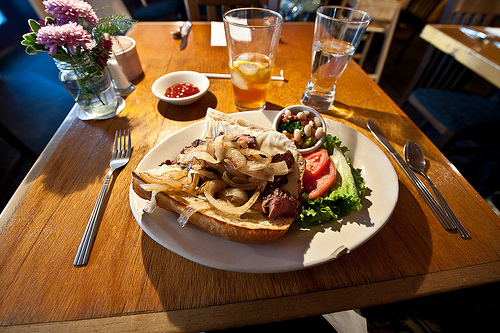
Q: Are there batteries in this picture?
A: No, there are no batteries.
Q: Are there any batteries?
A: No, there are no batteries.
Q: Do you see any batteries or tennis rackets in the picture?
A: No, there are no batteries or tennis rackets.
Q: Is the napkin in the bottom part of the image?
A: No, the napkin is in the top of the image.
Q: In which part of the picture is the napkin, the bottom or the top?
A: The napkin is in the top of the image.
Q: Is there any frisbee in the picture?
A: No, there are no frisbees.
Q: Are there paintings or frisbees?
A: No, there are no frisbees or paintings.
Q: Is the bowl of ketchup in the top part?
A: Yes, the bowl is in the top of the image.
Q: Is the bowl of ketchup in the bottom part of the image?
A: No, the bowl is in the top of the image.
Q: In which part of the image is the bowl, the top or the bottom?
A: The bowl is in the top of the image.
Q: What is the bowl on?
A: The bowl is on the table.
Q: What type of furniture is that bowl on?
A: The bowl is on the table.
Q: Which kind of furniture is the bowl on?
A: The bowl is on the table.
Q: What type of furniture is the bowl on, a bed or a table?
A: The bowl is on a table.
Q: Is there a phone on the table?
A: No, there is a bowl on the table.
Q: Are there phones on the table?
A: No, there is a bowl on the table.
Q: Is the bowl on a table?
A: Yes, the bowl is on a table.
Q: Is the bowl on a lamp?
A: No, the bowl is on a table.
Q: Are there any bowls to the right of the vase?
A: Yes, there is a bowl to the right of the vase.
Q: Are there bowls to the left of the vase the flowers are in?
A: No, the bowl is to the right of the vase.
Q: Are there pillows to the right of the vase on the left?
A: No, there is a bowl to the right of the vase.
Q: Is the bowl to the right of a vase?
A: Yes, the bowl is to the right of a vase.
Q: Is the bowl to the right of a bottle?
A: No, the bowl is to the right of a vase.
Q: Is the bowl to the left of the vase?
A: No, the bowl is to the right of the vase.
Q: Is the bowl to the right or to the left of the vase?
A: The bowl is to the right of the vase.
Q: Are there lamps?
A: No, there are no lamps.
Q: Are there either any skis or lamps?
A: No, there are no lamps or skis.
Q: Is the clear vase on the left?
A: Yes, the vase is on the left of the image.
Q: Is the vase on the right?
A: No, the vase is on the left of the image.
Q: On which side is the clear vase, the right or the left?
A: The vase is on the left of the image.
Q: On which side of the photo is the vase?
A: The vase is on the left of the image.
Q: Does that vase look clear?
A: Yes, the vase is clear.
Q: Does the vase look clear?
A: Yes, the vase is clear.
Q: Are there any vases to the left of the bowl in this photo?
A: Yes, there is a vase to the left of the bowl.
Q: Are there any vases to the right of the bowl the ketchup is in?
A: No, the vase is to the left of the bowl.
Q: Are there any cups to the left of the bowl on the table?
A: No, there is a vase to the left of the bowl.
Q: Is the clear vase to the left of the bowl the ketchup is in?
A: Yes, the vase is to the left of the bowl.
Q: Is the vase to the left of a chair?
A: No, the vase is to the left of the bowl.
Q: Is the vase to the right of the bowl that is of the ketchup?
A: No, the vase is to the left of the bowl.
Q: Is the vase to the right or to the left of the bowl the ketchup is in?
A: The vase is to the left of the bowl.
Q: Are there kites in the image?
A: No, there are no kites.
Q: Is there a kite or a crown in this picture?
A: No, there are no kites or crowns.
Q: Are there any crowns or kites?
A: No, there are no kites or crowns.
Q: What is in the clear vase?
A: The flowers are in the vase.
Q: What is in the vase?
A: The flowers are in the vase.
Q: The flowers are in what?
A: The flowers are in the vase.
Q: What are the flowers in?
A: The flowers are in the vase.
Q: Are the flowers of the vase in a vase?
A: Yes, the flowers are in a vase.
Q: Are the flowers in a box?
A: No, the flowers are in a vase.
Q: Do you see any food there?
A: Yes, there is food.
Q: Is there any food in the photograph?
A: Yes, there is food.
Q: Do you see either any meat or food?
A: Yes, there is food.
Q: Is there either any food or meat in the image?
A: Yes, there is food.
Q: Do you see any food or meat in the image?
A: Yes, there is food.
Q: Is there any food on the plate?
A: Yes, there is food on the plate.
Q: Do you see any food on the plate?
A: Yes, there is food on the plate.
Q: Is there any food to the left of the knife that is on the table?
A: Yes, there is food to the left of the knife.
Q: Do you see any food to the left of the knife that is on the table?
A: Yes, there is food to the left of the knife.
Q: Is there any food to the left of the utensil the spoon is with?
A: Yes, there is food to the left of the knife.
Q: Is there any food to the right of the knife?
A: No, the food is to the left of the knife.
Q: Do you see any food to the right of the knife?
A: No, the food is to the left of the knife.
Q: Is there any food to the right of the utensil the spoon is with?
A: No, the food is to the left of the knife.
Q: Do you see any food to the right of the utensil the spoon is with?
A: No, the food is to the left of the knife.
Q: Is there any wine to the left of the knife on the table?
A: No, there is food to the left of the knife.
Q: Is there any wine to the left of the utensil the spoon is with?
A: No, there is food to the left of the knife.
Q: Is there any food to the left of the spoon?
A: Yes, there is food to the left of the spoon.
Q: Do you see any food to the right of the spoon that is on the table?
A: No, the food is to the left of the spoon.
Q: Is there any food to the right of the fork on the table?
A: Yes, there is food to the right of the fork.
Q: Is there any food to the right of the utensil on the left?
A: Yes, there is food to the right of the fork.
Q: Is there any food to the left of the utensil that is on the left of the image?
A: No, the food is to the right of the fork.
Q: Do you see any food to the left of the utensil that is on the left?
A: No, the food is to the right of the fork.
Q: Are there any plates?
A: Yes, there is a plate.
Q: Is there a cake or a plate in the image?
A: Yes, there is a plate.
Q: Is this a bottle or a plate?
A: This is a plate.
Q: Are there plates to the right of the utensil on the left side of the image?
A: Yes, there is a plate to the right of the fork.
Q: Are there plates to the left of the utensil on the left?
A: No, the plate is to the right of the fork.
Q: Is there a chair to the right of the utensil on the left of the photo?
A: No, there is a plate to the right of the fork.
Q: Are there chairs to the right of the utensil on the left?
A: No, there is a plate to the right of the fork.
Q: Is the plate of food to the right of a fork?
A: Yes, the plate is to the right of a fork.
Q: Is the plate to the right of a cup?
A: No, the plate is to the right of a fork.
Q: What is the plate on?
A: The plate is on the table.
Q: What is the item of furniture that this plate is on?
A: The piece of furniture is a table.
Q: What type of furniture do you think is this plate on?
A: The plate is on the table.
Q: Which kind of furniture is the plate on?
A: The plate is on the table.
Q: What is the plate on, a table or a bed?
A: The plate is on a table.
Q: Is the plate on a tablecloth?
A: No, the plate is on a table.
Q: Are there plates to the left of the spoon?
A: Yes, there is a plate to the left of the spoon.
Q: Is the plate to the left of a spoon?
A: Yes, the plate is to the left of a spoon.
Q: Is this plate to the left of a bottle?
A: No, the plate is to the left of a spoon.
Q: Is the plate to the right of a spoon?
A: No, the plate is to the left of a spoon.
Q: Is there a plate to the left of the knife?
A: Yes, there is a plate to the left of the knife.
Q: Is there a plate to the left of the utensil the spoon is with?
A: Yes, there is a plate to the left of the knife.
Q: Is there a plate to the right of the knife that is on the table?
A: No, the plate is to the left of the knife.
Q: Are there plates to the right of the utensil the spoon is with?
A: No, the plate is to the left of the knife.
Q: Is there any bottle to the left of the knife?
A: No, there is a plate to the left of the knife.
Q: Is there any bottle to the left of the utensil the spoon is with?
A: No, there is a plate to the left of the knife.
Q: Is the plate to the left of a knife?
A: Yes, the plate is to the left of a knife.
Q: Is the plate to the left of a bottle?
A: No, the plate is to the left of a knife.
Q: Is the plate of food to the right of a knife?
A: No, the plate is to the left of a knife.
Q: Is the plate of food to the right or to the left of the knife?
A: The plate is to the left of the knife.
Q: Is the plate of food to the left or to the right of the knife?
A: The plate is to the left of the knife.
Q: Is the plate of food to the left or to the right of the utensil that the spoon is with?
A: The plate is to the left of the knife.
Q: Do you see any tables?
A: Yes, there is a table.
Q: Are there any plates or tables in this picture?
A: Yes, there is a table.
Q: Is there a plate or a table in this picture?
A: Yes, there is a table.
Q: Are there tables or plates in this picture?
A: Yes, there is a table.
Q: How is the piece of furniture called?
A: The piece of furniture is a table.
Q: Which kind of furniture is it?
A: The piece of furniture is a table.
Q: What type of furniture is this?
A: This is a table.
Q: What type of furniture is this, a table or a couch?
A: This is a table.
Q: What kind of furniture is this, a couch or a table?
A: This is a table.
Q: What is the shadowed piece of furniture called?
A: The piece of furniture is a table.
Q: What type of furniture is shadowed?
A: The furniture is a table.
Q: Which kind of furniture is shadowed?
A: The furniture is a table.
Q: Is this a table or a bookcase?
A: This is a table.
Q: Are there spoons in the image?
A: Yes, there is a spoon.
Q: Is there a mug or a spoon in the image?
A: Yes, there is a spoon.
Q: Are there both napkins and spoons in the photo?
A: Yes, there are both a spoon and a napkin.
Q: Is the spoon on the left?
A: No, the spoon is on the right of the image.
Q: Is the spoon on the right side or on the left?
A: The spoon is on the right of the image.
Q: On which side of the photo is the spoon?
A: The spoon is on the right of the image.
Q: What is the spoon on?
A: The spoon is on the table.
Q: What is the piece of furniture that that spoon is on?
A: The piece of furniture is a table.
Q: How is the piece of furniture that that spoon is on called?
A: The piece of furniture is a table.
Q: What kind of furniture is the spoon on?
A: The spoon is on the table.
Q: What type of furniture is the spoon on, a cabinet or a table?
A: The spoon is on a table.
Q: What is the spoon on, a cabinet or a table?
A: The spoon is on a table.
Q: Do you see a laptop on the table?
A: No, there is a spoon on the table.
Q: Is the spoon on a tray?
A: No, the spoon is on a table.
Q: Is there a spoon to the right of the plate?
A: Yes, there is a spoon to the right of the plate.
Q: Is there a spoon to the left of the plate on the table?
A: No, the spoon is to the right of the plate.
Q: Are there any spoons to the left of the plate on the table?
A: No, the spoon is to the right of the plate.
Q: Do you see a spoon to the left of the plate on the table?
A: No, the spoon is to the right of the plate.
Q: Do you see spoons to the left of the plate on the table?
A: No, the spoon is to the right of the plate.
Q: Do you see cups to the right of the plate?
A: No, there is a spoon to the right of the plate.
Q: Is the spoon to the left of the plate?
A: No, the spoon is to the right of the plate.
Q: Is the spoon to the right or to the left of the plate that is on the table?
A: The spoon is to the right of the plate.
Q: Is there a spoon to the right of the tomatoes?
A: Yes, there is a spoon to the right of the tomatoes.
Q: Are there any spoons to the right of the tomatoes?
A: Yes, there is a spoon to the right of the tomatoes.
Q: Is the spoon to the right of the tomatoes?
A: Yes, the spoon is to the right of the tomatoes.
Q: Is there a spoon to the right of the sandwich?
A: Yes, there is a spoon to the right of the sandwich.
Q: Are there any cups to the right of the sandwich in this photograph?
A: No, there is a spoon to the right of the sandwich.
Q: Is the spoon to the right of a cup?
A: No, the spoon is to the right of a sandwich.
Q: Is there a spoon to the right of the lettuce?
A: Yes, there is a spoon to the right of the lettuce.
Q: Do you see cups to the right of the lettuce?
A: No, there is a spoon to the right of the lettuce.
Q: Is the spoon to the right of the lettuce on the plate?
A: Yes, the spoon is to the right of the lettuce.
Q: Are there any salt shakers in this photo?
A: No, there are no salt shakers.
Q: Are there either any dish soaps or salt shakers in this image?
A: No, there are no salt shakers or dish soaps.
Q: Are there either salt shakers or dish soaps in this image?
A: No, there are no salt shakers or dish soaps.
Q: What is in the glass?
A: The liquid is in the glass.